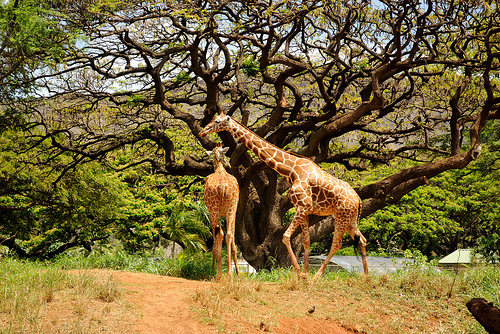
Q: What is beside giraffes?
A: Large tree with curved branches.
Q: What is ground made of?
A: Dirt and grass.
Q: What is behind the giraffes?
A: A tree.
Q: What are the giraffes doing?
A: Eating.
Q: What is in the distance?
A: Mountains.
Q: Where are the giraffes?
A: In front of the tree.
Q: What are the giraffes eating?
A: Leaves.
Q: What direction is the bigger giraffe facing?
A: Left.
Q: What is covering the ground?
A: Dirt patches and grass.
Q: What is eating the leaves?
A: Giraffes.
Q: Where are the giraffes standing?
A: Near the tree.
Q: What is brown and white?
A: The giraffes.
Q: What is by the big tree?
A: Two giraffes.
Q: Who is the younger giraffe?
A: The one with back to camera.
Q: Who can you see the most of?
A: The giraffe on the left.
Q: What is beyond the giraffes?
A: A tree.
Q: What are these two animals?
A: Giraffes.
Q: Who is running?
A: The giraffe.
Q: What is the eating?
A: Leaves from the tree.